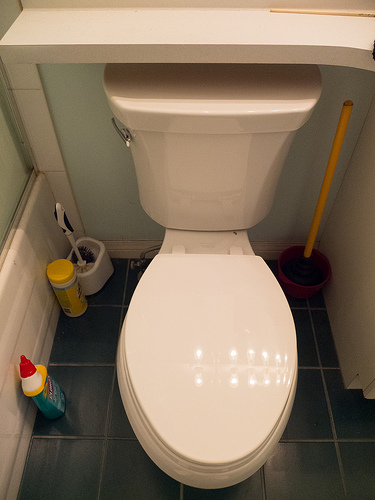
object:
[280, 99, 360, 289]
toilet plunger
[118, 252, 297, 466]
toilet lid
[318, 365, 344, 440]
line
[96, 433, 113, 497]
line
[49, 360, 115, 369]
line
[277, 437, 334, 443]
line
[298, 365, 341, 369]
line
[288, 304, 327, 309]
line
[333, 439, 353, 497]
line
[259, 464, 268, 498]
line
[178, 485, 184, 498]
line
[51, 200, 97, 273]
toilet brush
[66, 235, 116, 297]
container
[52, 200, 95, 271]
brush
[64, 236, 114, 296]
stand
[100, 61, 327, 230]
toilet tank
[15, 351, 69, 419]
bottle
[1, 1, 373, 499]
bathroom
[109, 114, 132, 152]
toilet flusher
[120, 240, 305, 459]
seat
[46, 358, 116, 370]
groutline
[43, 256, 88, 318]
cleaner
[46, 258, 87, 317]
bottle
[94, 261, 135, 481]
white groutline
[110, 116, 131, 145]
toilet handle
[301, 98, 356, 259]
handle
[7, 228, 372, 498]
blue tile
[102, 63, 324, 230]
reservoir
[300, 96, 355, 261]
black yellow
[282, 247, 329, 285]
plunger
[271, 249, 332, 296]
bowl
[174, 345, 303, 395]
lights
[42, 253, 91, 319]
container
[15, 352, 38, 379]
red cap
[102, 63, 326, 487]
toilet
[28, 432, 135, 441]
grout line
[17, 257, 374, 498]
floor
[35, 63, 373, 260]
wall